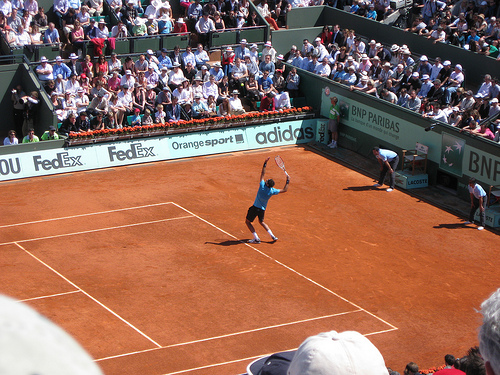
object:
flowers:
[300, 104, 310, 110]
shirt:
[252, 181, 279, 209]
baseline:
[171, 202, 397, 330]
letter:
[125, 142, 137, 161]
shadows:
[341, 181, 386, 193]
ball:
[238, 81, 245, 87]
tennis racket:
[273, 152, 289, 177]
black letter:
[115, 149, 126, 161]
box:
[392, 170, 431, 190]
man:
[326, 94, 344, 148]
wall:
[276, 59, 500, 209]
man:
[243, 155, 291, 243]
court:
[0, 139, 500, 374]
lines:
[95, 310, 365, 363]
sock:
[252, 232, 258, 241]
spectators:
[34, 54, 54, 81]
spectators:
[192, 42, 208, 64]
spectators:
[417, 74, 432, 97]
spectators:
[467, 30, 479, 44]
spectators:
[310, 36, 329, 58]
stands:
[0, 0, 500, 180]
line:
[2, 201, 173, 229]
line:
[170, 326, 398, 374]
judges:
[464, 176, 488, 232]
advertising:
[0, 116, 320, 183]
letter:
[255, 130, 267, 145]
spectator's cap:
[284, 327, 388, 374]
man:
[371, 144, 401, 192]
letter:
[50, 157, 60, 172]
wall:
[0, 116, 319, 184]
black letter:
[33, 155, 44, 171]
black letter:
[50, 158, 65, 169]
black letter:
[8, 155, 21, 174]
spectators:
[68, 25, 91, 59]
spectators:
[289, 46, 301, 65]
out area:
[0, 0, 320, 154]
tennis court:
[0, 140, 500, 374]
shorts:
[245, 204, 266, 224]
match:
[0, 0, 500, 374]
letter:
[467, 151, 482, 175]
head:
[284, 330, 391, 374]